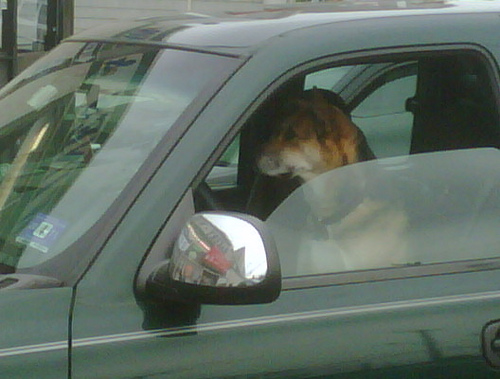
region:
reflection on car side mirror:
[161, 197, 269, 312]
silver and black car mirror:
[133, 196, 284, 335]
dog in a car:
[250, 52, 400, 240]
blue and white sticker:
[3, 187, 62, 260]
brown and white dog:
[254, 93, 366, 198]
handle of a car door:
[473, 310, 498, 367]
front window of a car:
[1, 62, 183, 222]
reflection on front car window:
[0, 51, 205, 233]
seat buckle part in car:
[388, 65, 475, 149]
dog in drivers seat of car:
[101, 24, 428, 329]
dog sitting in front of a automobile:
[257, 83, 412, 275]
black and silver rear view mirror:
[149, 210, 281, 305]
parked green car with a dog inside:
[3, 0, 498, 377]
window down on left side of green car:
[203, 46, 498, 281]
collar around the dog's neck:
[310, 197, 362, 240]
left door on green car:
[69, 10, 499, 375]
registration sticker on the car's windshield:
[15, 210, 67, 253]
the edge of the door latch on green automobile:
[481, 318, 498, 363]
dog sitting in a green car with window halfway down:
[2, 2, 499, 377]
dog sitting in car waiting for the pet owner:
[0, 0, 498, 376]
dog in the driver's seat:
[248, 77, 409, 279]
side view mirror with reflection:
[127, 200, 307, 314]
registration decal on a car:
[7, 206, 82, 258]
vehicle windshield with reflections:
[6, 53, 192, 235]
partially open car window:
[271, 147, 496, 278]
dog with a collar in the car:
[235, 78, 408, 250]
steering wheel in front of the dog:
[193, 183, 225, 210]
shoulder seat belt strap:
[401, 94, 448, 120]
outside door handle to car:
[477, 311, 498, 370]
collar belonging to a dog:
[304, 173, 394, 241]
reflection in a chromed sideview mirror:
[165, 207, 265, 289]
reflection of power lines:
[363, 315, 493, 377]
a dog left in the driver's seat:
[248, 87, 406, 268]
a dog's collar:
[296, 175, 407, 220]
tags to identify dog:
[300, 218, 335, 248]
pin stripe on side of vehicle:
[0, 281, 499, 359]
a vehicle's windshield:
[1, 32, 258, 291]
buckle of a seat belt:
[402, 86, 436, 121]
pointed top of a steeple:
[225, 241, 251, 288]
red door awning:
[201, 244, 234, 279]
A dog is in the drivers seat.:
[236, 85, 488, 301]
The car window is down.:
[175, 37, 498, 282]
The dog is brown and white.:
[224, 67, 462, 308]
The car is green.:
[47, 15, 497, 374]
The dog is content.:
[247, 81, 444, 278]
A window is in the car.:
[10, 40, 249, 274]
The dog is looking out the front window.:
[228, 58, 436, 286]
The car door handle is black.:
[471, 298, 496, 376]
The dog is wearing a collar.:
[297, 161, 409, 253]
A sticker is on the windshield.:
[9, 199, 85, 273]